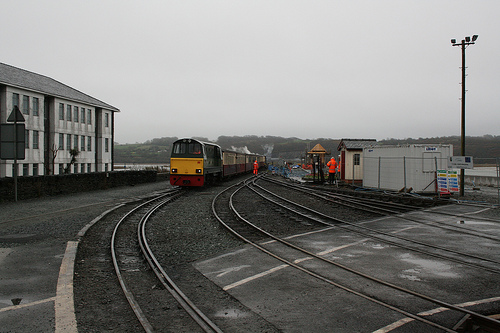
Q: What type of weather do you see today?
A: It is overcast.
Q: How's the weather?
A: It is overcast.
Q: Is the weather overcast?
A: Yes, it is overcast.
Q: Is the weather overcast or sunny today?
A: It is overcast.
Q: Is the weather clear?
A: No, it is overcast.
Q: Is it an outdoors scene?
A: Yes, it is outdoors.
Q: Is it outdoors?
A: Yes, it is outdoors.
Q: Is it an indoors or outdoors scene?
A: It is outdoors.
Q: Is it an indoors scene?
A: No, it is outdoors.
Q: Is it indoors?
A: No, it is outdoors.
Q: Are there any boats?
A: No, there are no boats.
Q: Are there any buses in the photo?
A: No, there are no buses.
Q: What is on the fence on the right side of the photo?
A: The sign is on the fence.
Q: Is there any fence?
A: Yes, there is a fence.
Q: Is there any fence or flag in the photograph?
A: Yes, there is a fence.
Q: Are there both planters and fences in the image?
A: No, there is a fence but no planters.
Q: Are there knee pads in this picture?
A: No, there are no knee pads.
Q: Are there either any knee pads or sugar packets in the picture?
A: No, there are no knee pads or sugar packets.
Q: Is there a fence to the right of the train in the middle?
A: Yes, there is a fence to the right of the train.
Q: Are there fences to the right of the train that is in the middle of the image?
A: Yes, there is a fence to the right of the train.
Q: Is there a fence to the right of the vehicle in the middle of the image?
A: Yes, there is a fence to the right of the train.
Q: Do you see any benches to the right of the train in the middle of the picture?
A: No, there is a fence to the right of the train.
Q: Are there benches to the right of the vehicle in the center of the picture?
A: No, there is a fence to the right of the train.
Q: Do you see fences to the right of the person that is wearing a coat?
A: Yes, there is a fence to the right of the person.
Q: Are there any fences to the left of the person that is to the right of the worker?
A: No, the fence is to the right of the person.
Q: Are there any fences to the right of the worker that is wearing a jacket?
A: Yes, there is a fence to the right of the worker.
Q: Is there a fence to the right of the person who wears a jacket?
A: Yes, there is a fence to the right of the worker.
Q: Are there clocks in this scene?
A: No, there are no clocks.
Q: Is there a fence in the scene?
A: Yes, there is a fence.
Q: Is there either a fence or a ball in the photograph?
A: Yes, there is a fence.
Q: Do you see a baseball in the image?
A: No, there are no baseballs.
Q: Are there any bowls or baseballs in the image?
A: No, there are no baseballs or bowls.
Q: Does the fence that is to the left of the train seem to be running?
A: Yes, the fence is running.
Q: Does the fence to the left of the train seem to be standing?
A: No, the fence is running.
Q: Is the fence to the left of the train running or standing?
A: The fence is running.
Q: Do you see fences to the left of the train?
A: Yes, there is a fence to the left of the train.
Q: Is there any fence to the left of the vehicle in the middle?
A: Yes, there is a fence to the left of the train.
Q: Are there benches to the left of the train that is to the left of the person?
A: No, there is a fence to the left of the train.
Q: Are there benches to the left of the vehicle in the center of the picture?
A: No, there is a fence to the left of the train.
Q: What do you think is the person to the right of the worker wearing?
A: The person is wearing a coat.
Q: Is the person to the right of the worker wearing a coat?
A: Yes, the person is wearing a coat.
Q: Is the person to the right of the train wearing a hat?
A: No, the person is wearing a coat.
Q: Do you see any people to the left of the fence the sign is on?
A: Yes, there is a person to the left of the fence.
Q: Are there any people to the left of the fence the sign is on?
A: Yes, there is a person to the left of the fence.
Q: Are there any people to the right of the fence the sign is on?
A: No, the person is to the left of the fence.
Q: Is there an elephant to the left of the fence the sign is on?
A: No, there is a person to the left of the fence.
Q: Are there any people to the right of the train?
A: Yes, there is a person to the right of the train.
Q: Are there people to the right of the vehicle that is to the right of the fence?
A: Yes, there is a person to the right of the train.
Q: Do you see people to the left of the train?
A: No, the person is to the right of the train.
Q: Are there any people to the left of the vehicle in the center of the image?
A: No, the person is to the right of the train.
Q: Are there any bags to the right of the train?
A: No, there is a person to the right of the train.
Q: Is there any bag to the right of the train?
A: No, there is a person to the right of the train.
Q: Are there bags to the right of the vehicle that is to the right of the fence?
A: No, there is a person to the right of the train.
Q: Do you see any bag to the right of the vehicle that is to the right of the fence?
A: No, there is a person to the right of the train.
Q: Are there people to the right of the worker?
A: Yes, there is a person to the right of the worker.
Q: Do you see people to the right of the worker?
A: Yes, there is a person to the right of the worker.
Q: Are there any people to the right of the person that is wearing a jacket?
A: Yes, there is a person to the right of the worker.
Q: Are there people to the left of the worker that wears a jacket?
A: No, the person is to the right of the worker.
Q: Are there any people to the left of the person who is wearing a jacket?
A: No, the person is to the right of the worker.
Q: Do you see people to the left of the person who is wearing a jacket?
A: No, the person is to the right of the worker.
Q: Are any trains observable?
A: Yes, there is a train.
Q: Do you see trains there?
A: Yes, there is a train.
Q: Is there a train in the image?
A: Yes, there is a train.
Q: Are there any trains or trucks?
A: Yes, there is a train.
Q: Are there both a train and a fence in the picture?
A: Yes, there are both a train and a fence.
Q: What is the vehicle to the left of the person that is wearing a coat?
A: The vehicle is a train.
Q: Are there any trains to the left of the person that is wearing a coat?
A: Yes, there is a train to the left of the person.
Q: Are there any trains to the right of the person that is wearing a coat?
A: No, the train is to the left of the person.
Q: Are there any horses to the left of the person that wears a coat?
A: No, there is a train to the left of the person.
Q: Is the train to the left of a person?
A: Yes, the train is to the left of a person.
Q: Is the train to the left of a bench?
A: No, the train is to the left of a person.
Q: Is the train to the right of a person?
A: No, the train is to the left of a person.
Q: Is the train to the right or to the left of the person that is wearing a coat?
A: The train is to the left of the person.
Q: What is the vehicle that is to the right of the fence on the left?
A: The vehicle is a train.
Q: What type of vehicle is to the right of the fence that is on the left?
A: The vehicle is a train.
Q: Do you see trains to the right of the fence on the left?
A: Yes, there is a train to the right of the fence.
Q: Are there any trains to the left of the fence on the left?
A: No, the train is to the right of the fence.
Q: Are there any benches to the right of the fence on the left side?
A: No, there is a train to the right of the fence.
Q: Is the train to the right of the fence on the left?
A: Yes, the train is to the right of the fence.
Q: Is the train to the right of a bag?
A: No, the train is to the right of the fence.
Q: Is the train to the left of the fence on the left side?
A: No, the train is to the right of the fence.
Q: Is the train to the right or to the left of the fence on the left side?
A: The train is to the right of the fence.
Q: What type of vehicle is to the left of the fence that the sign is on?
A: The vehicle is a train.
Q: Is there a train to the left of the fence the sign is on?
A: Yes, there is a train to the left of the fence.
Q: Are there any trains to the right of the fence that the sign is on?
A: No, the train is to the left of the fence.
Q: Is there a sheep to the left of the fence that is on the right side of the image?
A: No, there is a train to the left of the fence.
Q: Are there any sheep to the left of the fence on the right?
A: No, there is a train to the left of the fence.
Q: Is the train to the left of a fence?
A: Yes, the train is to the left of a fence.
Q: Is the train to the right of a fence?
A: No, the train is to the left of a fence.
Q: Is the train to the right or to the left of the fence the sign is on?
A: The train is to the left of the fence.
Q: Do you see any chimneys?
A: No, there are no chimneys.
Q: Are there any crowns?
A: No, there are no crowns.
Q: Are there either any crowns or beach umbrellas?
A: No, there are no crowns or beach umbrellas.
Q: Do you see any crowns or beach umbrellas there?
A: No, there are no crowns or beach umbrellas.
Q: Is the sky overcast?
A: Yes, the sky is overcast.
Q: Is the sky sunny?
A: No, the sky is overcast.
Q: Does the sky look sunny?
A: No, the sky is overcast.